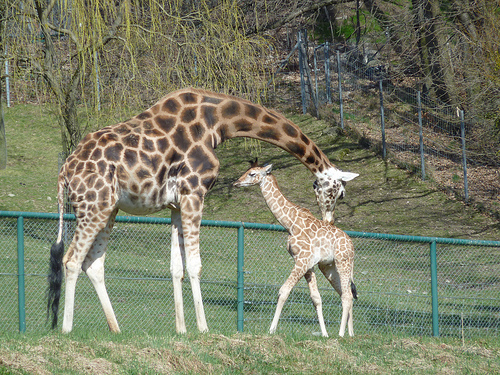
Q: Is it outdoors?
A: Yes, it is outdoors.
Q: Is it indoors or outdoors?
A: It is outdoors.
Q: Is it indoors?
A: No, it is outdoors.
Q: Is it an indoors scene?
A: No, it is outdoors.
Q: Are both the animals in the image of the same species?
A: Yes, all the animals are giraffes.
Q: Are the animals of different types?
A: No, all the animals are giraffes.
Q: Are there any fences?
A: Yes, there is a fence.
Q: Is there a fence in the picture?
A: Yes, there is a fence.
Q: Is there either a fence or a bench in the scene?
A: Yes, there is a fence.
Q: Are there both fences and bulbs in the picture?
A: No, there is a fence but no light bulbs.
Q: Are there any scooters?
A: No, there are no scooters.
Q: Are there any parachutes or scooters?
A: No, there are no scooters or parachutes.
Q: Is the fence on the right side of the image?
A: Yes, the fence is on the right of the image.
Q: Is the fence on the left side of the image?
A: No, the fence is on the right of the image.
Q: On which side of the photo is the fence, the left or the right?
A: The fence is on the right of the image.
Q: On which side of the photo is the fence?
A: The fence is on the right of the image.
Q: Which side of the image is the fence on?
A: The fence is on the right of the image.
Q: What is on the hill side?
A: The fence is on the hill side.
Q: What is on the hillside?
A: The fence is on the hill side.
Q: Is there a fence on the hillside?
A: Yes, there is a fence on the hillside.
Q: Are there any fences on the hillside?
A: Yes, there is a fence on the hillside.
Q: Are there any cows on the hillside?
A: No, there is a fence on the hillside.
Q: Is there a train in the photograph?
A: No, there are no trains.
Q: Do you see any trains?
A: No, there are no trains.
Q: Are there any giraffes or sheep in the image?
A: Yes, there is a giraffe.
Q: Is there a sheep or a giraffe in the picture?
A: Yes, there is a giraffe.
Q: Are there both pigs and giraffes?
A: No, there is a giraffe but no pigs.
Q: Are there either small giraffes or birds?
A: Yes, there is a small giraffe.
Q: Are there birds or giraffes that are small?
A: Yes, the giraffe is small.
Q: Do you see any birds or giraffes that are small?
A: Yes, the giraffe is small.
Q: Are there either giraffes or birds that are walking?
A: Yes, the giraffe is walking.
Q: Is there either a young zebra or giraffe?
A: Yes, there is a young giraffe.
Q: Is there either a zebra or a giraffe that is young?
A: Yes, the giraffe is young.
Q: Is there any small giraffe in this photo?
A: Yes, there is a small giraffe.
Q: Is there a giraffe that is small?
A: Yes, there is a giraffe that is small.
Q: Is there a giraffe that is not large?
A: Yes, there is a small giraffe.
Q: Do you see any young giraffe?
A: Yes, there is a young giraffe.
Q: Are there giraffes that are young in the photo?
A: Yes, there is a young giraffe.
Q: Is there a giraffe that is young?
A: Yes, there is a giraffe that is young.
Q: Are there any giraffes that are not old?
A: Yes, there is an young giraffe.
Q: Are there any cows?
A: No, there are no cows.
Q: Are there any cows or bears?
A: No, there are no cows or bears.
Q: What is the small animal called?
A: The animal is a giraffe.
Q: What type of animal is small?
A: The animal is a giraffe.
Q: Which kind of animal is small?
A: The animal is a giraffe.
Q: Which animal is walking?
A: The animal is a giraffe.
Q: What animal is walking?
A: The animal is a giraffe.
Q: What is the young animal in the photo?
A: The animal is a giraffe.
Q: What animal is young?
A: The animal is a giraffe.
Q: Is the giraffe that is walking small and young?
A: Yes, the giraffe is small and young.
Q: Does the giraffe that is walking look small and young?
A: Yes, the giraffe is small and young.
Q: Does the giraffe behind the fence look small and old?
A: No, the giraffe is small but young.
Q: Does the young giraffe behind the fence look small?
A: Yes, the giraffe is small.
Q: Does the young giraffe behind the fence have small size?
A: Yes, the giraffe is small.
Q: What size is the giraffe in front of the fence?
A: The giraffe is small.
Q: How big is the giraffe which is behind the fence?
A: The giraffe is small.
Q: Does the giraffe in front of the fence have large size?
A: No, the giraffe is small.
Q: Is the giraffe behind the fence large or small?
A: The giraffe is small.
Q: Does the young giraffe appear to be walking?
A: Yes, the giraffe is walking.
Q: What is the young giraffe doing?
A: The giraffe is walking.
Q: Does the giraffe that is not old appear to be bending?
A: No, the giraffe is walking.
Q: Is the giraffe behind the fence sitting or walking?
A: The giraffe is walking.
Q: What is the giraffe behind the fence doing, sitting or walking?
A: The giraffe is walking.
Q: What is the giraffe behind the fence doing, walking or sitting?
A: The giraffe is walking.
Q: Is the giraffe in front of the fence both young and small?
A: Yes, the giraffe is young and small.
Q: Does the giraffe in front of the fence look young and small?
A: Yes, the giraffe is young and small.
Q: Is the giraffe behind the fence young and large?
A: No, the giraffe is young but small.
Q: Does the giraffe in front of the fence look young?
A: Yes, the giraffe is young.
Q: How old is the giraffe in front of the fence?
A: The giraffe is young.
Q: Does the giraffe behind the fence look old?
A: No, the giraffe is young.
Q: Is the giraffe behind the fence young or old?
A: The giraffe is young.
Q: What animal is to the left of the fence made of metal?
A: The animal is a giraffe.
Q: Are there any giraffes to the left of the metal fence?
A: Yes, there is a giraffe to the left of the fence.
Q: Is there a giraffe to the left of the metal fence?
A: Yes, there is a giraffe to the left of the fence.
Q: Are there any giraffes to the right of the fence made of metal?
A: No, the giraffe is to the left of the fence.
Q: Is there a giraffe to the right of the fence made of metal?
A: No, the giraffe is to the left of the fence.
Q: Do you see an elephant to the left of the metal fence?
A: No, there is a giraffe to the left of the fence.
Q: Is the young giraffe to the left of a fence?
A: Yes, the giraffe is to the left of a fence.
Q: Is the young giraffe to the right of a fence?
A: No, the giraffe is to the left of a fence.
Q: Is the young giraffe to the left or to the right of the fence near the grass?
A: The giraffe is to the left of the fence.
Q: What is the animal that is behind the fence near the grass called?
A: The animal is a giraffe.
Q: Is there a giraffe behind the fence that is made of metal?
A: Yes, there is a giraffe behind the fence.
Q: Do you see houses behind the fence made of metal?
A: No, there is a giraffe behind the fence.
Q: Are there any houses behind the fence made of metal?
A: No, there is a giraffe behind the fence.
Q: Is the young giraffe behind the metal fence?
A: Yes, the giraffe is behind the fence.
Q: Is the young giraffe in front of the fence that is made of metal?
A: No, the giraffe is behind the fence.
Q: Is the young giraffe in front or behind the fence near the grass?
A: The giraffe is behind the fence.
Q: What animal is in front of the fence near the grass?
A: The giraffe is in front of the fence.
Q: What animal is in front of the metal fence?
A: The animal is a giraffe.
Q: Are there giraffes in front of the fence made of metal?
A: Yes, there is a giraffe in front of the fence.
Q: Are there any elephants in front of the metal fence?
A: No, there is a giraffe in front of the fence.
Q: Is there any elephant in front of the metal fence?
A: No, there is a giraffe in front of the fence.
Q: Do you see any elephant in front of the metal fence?
A: No, there is a giraffe in front of the fence.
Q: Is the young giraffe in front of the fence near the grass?
A: Yes, the giraffe is in front of the fence.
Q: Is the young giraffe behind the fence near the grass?
A: No, the giraffe is in front of the fence.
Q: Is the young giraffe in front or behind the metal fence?
A: The giraffe is in front of the fence.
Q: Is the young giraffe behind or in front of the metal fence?
A: The giraffe is in front of the fence.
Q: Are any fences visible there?
A: Yes, there is a fence.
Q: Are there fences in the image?
A: Yes, there is a fence.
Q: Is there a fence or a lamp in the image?
A: Yes, there is a fence.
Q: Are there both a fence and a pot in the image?
A: No, there is a fence but no pots.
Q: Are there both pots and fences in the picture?
A: No, there is a fence but no pots.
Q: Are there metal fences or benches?
A: Yes, there is a metal fence.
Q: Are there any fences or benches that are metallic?
A: Yes, the fence is metallic.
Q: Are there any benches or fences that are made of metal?
A: Yes, the fence is made of metal.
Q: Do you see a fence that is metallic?
A: Yes, there is a fence that is metallic.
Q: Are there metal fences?
A: Yes, there is a fence that is made of metal.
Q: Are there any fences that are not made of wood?
A: Yes, there is a fence that is made of metal.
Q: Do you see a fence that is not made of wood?
A: Yes, there is a fence that is made of metal.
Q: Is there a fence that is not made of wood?
A: Yes, there is a fence that is made of metal.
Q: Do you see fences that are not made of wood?
A: Yes, there is a fence that is made of metal.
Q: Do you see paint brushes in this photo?
A: No, there are no paint brushes.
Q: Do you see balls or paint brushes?
A: No, there are no paint brushes or balls.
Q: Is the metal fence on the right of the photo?
A: Yes, the fence is on the right of the image.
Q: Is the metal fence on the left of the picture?
A: No, the fence is on the right of the image.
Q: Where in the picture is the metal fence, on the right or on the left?
A: The fence is on the right of the image.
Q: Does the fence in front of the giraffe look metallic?
A: Yes, the fence is metallic.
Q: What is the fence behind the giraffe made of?
A: The fence is made of metal.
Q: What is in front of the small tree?
A: The fence is in front of the tree.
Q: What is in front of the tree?
A: The fence is in front of the tree.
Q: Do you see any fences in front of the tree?
A: Yes, there is a fence in front of the tree.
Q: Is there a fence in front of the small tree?
A: Yes, there is a fence in front of the tree.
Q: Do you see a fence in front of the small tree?
A: Yes, there is a fence in front of the tree.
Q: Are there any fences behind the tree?
A: No, the fence is in front of the tree.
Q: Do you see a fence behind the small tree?
A: No, the fence is in front of the tree.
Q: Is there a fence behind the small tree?
A: No, the fence is in front of the tree.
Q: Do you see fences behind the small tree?
A: No, the fence is in front of the tree.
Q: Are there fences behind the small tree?
A: No, the fence is in front of the tree.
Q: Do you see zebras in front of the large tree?
A: No, there is a fence in front of the tree.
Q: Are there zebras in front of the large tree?
A: No, there is a fence in front of the tree.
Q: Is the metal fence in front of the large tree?
A: Yes, the fence is in front of the tree.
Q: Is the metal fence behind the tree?
A: No, the fence is in front of the tree.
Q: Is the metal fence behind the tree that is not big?
A: No, the fence is in front of the tree.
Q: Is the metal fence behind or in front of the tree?
A: The fence is in front of the tree.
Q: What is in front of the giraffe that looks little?
A: The fence is in front of the giraffe.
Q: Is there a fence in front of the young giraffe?
A: Yes, there is a fence in front of the giraffe.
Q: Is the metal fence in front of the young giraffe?
A: Yes, the fence is in front of the giraffe.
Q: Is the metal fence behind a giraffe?
A: No, the fence is in front of a giraffe.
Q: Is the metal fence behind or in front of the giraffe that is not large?
A: The fence is in front of the giraffe.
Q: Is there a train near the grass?
A: No, there is a fence near the grass.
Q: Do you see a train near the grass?
A: No, there is a fence near the grass.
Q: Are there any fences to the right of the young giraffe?
A: Yes, there is a fence to the right of the giraffe.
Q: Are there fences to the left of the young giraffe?
A: No, the fence is to the right of the giraffe.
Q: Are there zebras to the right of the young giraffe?
A: No, there is a fence to the right of the giraffe.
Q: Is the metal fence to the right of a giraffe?
A: Yes, the fence is to the right of a giraffe.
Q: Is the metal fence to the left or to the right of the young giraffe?
A: The fence is to the right of the giraffe.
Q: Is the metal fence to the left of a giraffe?
A: No, the fence is to the right of a giraffe.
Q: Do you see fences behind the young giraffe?
A: Yes, there is a fence behind the giraffe.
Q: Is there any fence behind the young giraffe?
A: Yes, there is a fence behind the giraffe.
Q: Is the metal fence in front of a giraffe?
A: No, the fence is behind a giraffe.